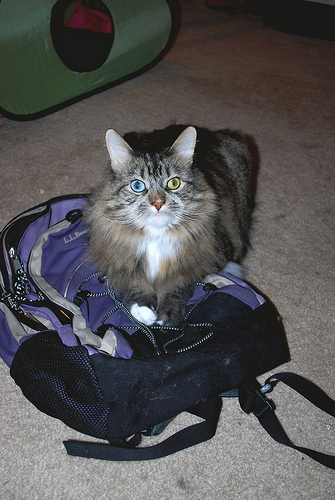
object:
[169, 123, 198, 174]
ears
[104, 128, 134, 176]
ears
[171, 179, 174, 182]
yelloweye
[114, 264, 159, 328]
leg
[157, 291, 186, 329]
leg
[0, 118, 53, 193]
ground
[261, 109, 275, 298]
mountain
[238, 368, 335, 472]
straps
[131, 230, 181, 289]
chest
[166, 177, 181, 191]
eye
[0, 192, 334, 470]
backpack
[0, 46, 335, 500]
carpet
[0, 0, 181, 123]
tent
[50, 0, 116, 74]
opening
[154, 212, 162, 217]
mouth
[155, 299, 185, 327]
grey paw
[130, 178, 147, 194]
eye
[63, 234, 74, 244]
l.l. bean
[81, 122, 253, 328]
cat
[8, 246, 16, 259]
zipper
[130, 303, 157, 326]
paw